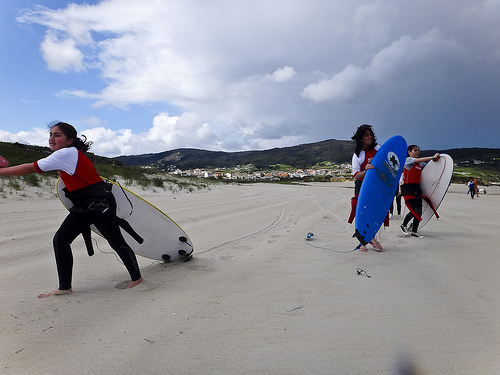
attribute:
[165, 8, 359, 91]
cloud — white, fluffy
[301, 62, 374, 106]
white cloud — fluffy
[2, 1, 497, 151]
sky — blue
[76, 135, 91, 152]
tail — pony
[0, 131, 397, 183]
hills — distant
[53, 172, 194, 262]
board — white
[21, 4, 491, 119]
sky — blue, white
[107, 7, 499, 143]
clouds — white